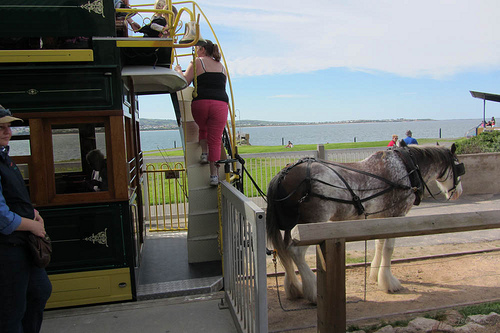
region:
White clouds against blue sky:
[244, 16, 479, 68]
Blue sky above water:
[260, 79, 458, 109]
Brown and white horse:
[279, 131, 477, 306]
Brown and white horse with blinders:
[271, 142, 482, 296]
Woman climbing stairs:
[181, 35, 245, 187]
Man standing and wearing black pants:
[5, 110, 64, 326]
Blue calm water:
[258, 117, 465, 137]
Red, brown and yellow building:
[41, 109, 171, 296]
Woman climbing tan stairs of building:
[162, 80, 246, 277]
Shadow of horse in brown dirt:
[411, 255, 496, 315]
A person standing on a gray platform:
[1, 104, 67, 331]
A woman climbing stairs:
[181, 40, 234, 192]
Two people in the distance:
[386, 126, 416, 147]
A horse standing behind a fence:
[264, 141, 469, 316]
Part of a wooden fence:
[283, 208, 499, 330]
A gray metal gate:
[218, 183, 275, 332]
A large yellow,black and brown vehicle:
[1, 0, 232, 311]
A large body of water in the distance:
[244, 119, 481, 140]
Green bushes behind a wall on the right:
[452, 133, 498, 154]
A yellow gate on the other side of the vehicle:
[138, 164, 189, 234]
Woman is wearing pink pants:
[188, 91, 247, 196]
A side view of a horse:
[254, 133, 487, 317]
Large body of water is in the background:
[100, 111, 498, 162]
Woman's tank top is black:
[178, 54, 250, 111]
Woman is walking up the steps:
[158, 26, 248, 263]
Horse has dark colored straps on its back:
[280, 142, 430, 223]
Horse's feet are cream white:
[270, 244, 457, 313]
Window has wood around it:
[23, 111, 140, 216]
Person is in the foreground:
[1, 97, 112, 331]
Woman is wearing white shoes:
[186, 146, 234, 203]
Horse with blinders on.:
[264, 135, 497, 317]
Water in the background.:
[1, 121, 498, 151]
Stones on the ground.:
[347, 313, 498, 328]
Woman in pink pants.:
[184, 36, 242, 186]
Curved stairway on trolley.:
[117, 6, 258, 281]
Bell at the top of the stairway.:
[173, 8, 213, 47]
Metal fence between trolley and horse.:
[215, 188, 277, 331]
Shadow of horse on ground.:
[272, 281, 496, 317]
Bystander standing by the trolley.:
[2, 101, 84, 326]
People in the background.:
[277, 125, 443, 148]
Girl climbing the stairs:
[184, 35, 225, 170]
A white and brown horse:
[250, 140, 472, 252]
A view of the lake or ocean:
[245, 96, 452, 153]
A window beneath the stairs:
[43, 83, 122, 228]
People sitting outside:
[377, 118, 422, 152]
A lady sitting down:
[0, 92, 14, 219]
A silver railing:
[180, 176, 286, 316]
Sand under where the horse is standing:
[236, 247, 484, 325]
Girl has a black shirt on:
[188, 67, 227, 137]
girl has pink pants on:
[185, 97, 226, 162]